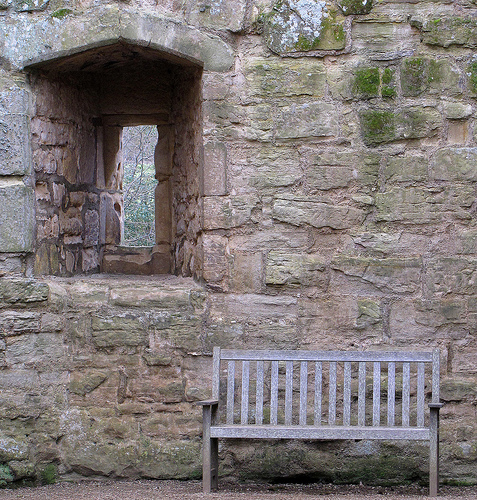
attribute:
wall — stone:
[0, 0, 476, 485]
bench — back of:
[193, 344, 443, 495]